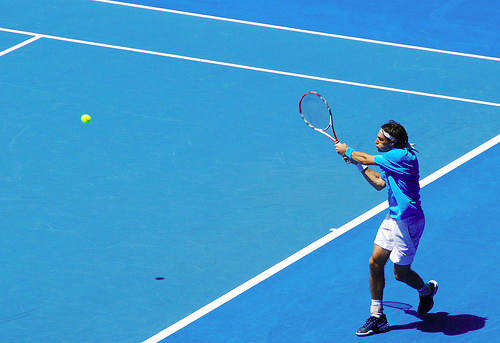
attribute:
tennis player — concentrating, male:
[332, 119, 440, 338]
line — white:
[106, 1, 498, 61]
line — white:
[1, 25, 499, 109]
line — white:
[127, 127, 499, 341]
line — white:
[1, 32, 42, 71]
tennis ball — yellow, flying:
[78, 111, 92, 127]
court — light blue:
[1, 0, 499, 343]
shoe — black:
[351, 311, 389, 338]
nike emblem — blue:
[375, 317, 387, 329]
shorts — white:
[372, 209, 426, 267]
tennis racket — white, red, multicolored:
[296, 88, 351, 164]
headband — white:
[377, 127, 401, 145]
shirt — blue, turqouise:
[374, 146, 424, 222]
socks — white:
[367, 283, 429, 319]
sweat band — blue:
[342, 145, 356, 161]